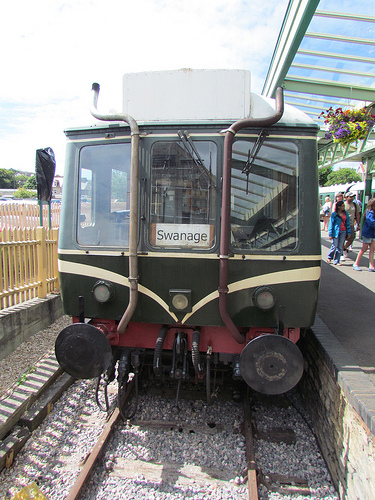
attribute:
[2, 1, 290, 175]
cloud — white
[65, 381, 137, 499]
track — brown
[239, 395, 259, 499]
track — brown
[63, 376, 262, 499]
tracks — train tracks, railway tracks, brown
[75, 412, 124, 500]
side — dark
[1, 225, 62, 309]
fence — wooden, wood, brown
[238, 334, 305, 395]
stopper — black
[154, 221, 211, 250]
sign — white, swanage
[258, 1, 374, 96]
awning — white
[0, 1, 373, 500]
photo — here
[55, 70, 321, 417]
train — green, blue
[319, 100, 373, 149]
flowers — colorful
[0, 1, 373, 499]
day — sunny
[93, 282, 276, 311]
lights — head lights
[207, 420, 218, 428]
wood — small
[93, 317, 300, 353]
color — red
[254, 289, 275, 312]
light — small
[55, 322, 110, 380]
disc — circular, black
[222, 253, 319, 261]
line — white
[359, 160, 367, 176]
pipe — red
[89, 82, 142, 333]
pipe — brown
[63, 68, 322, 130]
top — white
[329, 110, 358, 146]
basket — hanging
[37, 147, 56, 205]
bag — plastic